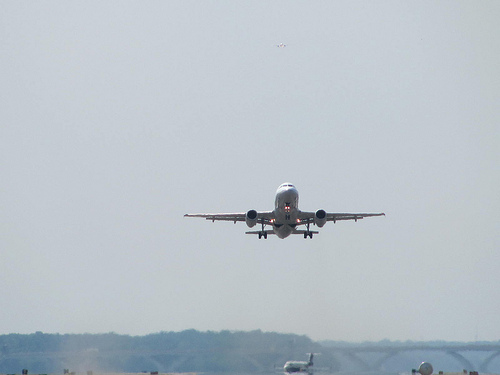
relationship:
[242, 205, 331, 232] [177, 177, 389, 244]
engines on airplane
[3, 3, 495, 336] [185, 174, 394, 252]
sky above airplanes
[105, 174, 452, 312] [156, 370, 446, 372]
airplane on a runway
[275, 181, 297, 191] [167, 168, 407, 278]
windows on airplane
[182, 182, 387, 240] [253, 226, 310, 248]
airplane flying wheels